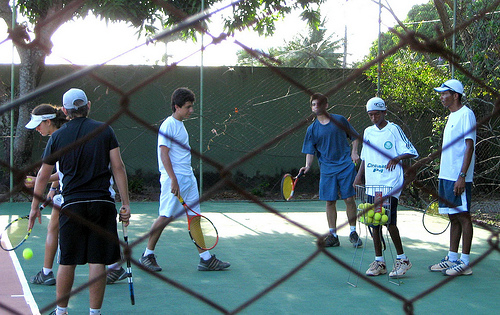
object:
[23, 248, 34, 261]
ball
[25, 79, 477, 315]
people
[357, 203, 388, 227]
balls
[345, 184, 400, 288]
basket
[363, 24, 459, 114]
plant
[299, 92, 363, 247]
boy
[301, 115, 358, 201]
blue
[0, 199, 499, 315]
ground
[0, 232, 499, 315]
shadow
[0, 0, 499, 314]
fence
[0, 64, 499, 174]
wall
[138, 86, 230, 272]
man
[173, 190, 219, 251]
racket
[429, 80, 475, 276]
man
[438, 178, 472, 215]
shorts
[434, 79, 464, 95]
cap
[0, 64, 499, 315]
court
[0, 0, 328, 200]
tree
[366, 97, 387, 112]
cap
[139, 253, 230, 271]
shoes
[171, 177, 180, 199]
hand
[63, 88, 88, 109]
hat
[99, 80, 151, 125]
link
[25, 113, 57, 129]
visor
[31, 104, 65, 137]
head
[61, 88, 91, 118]
head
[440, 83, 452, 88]
glasses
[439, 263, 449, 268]
stripes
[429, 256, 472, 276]
shoes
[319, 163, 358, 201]
shorts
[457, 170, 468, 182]
wrist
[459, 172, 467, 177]
watch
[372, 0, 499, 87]
tree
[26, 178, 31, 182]
ball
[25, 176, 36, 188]
hand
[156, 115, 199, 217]
white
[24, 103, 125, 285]
woman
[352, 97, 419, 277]
person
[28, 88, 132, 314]
man